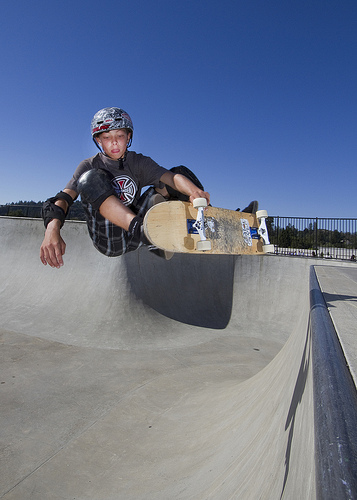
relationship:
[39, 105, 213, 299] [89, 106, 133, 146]
boy wearing helmet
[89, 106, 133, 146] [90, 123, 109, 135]
helmet has letters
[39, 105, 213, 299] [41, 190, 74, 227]
boy has elbow pad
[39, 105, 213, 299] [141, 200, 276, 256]
boy riding skateboard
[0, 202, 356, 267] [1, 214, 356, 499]
railing around ramp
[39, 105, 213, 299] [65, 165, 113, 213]
boy wearing pad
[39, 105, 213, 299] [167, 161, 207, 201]
boy wearing knee pad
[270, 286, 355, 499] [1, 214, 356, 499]
shadow on ramp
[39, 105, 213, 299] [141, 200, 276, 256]
boy holding skateboard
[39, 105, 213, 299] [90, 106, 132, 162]
boy has head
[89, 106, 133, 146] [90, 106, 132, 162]
helmet on head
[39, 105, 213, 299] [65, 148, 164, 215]
boy wearing shirt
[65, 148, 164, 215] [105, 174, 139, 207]
shirt has emblem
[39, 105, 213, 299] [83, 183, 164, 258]
boy wearing shorts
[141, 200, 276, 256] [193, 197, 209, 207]
skateboard has wheel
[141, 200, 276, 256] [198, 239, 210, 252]
skateboard has wheel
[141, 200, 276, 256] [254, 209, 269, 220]
skateboard has wheel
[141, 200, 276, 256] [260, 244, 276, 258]
skateboard has wheel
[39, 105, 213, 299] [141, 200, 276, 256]
boy on a skateboard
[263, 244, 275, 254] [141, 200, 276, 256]
wheel on skateboard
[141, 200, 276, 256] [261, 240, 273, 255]
skateboard with wheel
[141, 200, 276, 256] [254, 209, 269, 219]
skateboard with wheel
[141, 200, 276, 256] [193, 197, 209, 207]
skateboard with wheel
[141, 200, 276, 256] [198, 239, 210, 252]
skateboard with wheel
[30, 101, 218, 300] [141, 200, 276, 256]
boy riding skateboard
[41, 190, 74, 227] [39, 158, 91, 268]
elbow pad on boys arm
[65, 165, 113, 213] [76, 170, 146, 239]
pad on leg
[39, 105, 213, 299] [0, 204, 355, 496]
boy at park